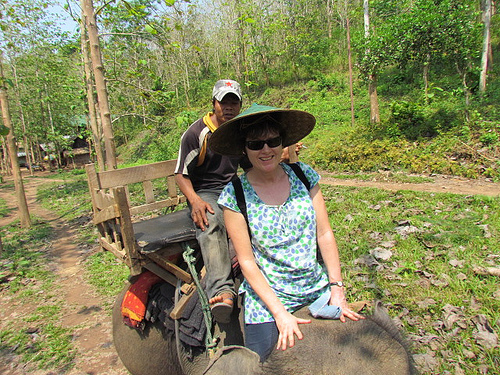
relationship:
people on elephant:
[175, 77, 365, 358] [110, 267, 425, 375]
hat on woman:
[207, 101, 318, 159] [216, 112, 366, 360]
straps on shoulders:
[225, 160, 311, 228] [215, 163, 327, 213]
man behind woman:
[173, 75, 304, 321] [216, 112, 366, 360]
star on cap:
[223, 80, 234, 90] [211, 78, 246, 107]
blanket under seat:
[120, 266, 172, 332] [80, 160, 200, 280]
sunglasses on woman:
[245, 136, 284, 151] [216, 112, 366, 360]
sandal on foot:
[210, 299, 234, 327] [207, 290, 236, 323]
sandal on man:
[210, 299, 234, 327] [173, 75, 304, 321]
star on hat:
[223, 80, 234, 90] [207, 101, 318, 159]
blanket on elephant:
[120, 266, 172, 332] [110, 267, 425, 375]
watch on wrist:
[326, 279, 347, 289] [326, 273, 346, 297]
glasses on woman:
[245, 136, 284, 151] [216, 112, 366, 360]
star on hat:
[223, 80, 234, 90] [211, 78, 246, 107]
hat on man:
[211, 78, 246, 107] [173, 75, 304, 321]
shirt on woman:
[216, 161, 336, 325] [216, 112, 366, 360]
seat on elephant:
[80, 160, 200, 280] [110, 267, 425, 375]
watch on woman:
[326, 279, 347, 289] [216, 112, 366, 360]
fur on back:
[262, 315, 413, 372] [125, 257, 409, 374]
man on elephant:
[173, 75, 304, 321] [110, 267, 425, 375]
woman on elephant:
[216, 112, 366, 360] [110, 267, 425, 375]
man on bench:
[173, 75, 304, 321] [80, 160, 200, 280]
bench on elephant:
[80, 160, 200, 280] [110, 267, 425, 375]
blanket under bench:
[120, 266, 172, 332] [80, 160, 200, 280]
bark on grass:
[352, 222, 494, 357] [341, 190, 498, 370]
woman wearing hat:
[216, 112, 366, 360] [207, 101, 318, 159]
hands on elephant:
[273, 300, 367, 353] [110, 267, 425, 375]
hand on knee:
[187, 198, 218, 234] [193, 205, 228, 239]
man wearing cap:
[173, 75, 304, 321] [211, 78, 246, 107]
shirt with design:
[216, 161, 336, 325] [216, 161, 336, 325]